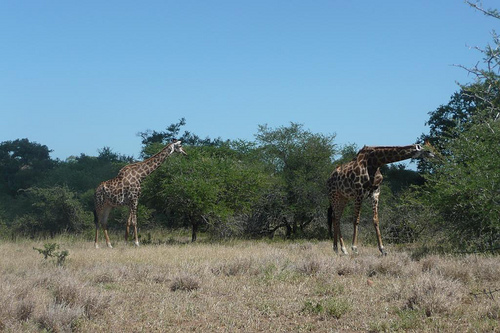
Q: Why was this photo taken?
A: To document giraffes outdoors.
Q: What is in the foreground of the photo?
A: Grass.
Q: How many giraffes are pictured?
A: Two.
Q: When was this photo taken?
A: Daytime.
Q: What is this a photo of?
A: Two giraffes.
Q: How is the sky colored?
A: Blue.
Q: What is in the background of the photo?
A: Trees and blue sky.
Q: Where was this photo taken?
A: In the wild.